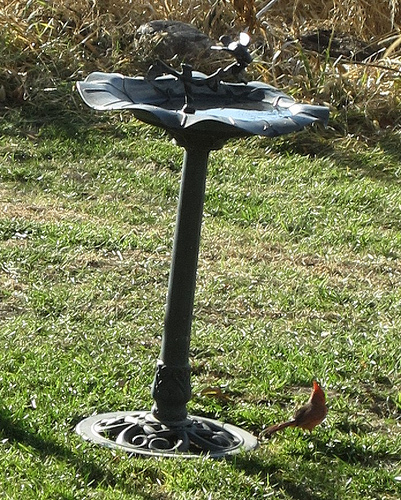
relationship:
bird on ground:
[267, 378, 339, 444] [238, 270, 356, 319]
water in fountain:
[188, 96, 237, 111] [97, 32, 274, 153]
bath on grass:
[76, 30, 329, 135] [42, 140, 116, 163]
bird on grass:
[267, 378, 339, 444] [42, 140, 116, 163]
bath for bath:
[76, 30, 329, 135] [76, 30, 329, 135]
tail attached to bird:
[255, 416, 297, 435] [267, 378, 339, 444]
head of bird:
[292, 378, 332, 403] [267, 378, 339, 444]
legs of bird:
[291, 423, 313, 440] [267, 378, 339, 444]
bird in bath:
[267, 378, 339, 444] [149, 99, 265, 145]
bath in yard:
[76, 30, 329, 135] [234, 150, 344, 218]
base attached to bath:
[140, 392, 188, 440] [76, 30, 329, 135]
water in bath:
[188, 96, 237, 111] [76, 30, 329, 135]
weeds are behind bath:
[277, 45, 312, 67] [76, 30, 329, 135]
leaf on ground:
[208, 386, 232, 401] [238, 270, 356, 319]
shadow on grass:
[277, 143, 319, 170] [42, 140, 116, 163]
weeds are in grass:
[277, 45, 312, 67] [42, 140, 116, 163]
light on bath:
[208, 97, 290, 130] [76, 30, 329, 135]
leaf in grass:
[208, 386, 232, 401] [42, 140, 116, 163]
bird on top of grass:
[267, 378, 339, 444] [42, 140, 116, 163]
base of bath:
[140, 392, 188, 440] [149, 99, 265, 145]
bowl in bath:
[36, 72, 227, 127] [76, 30, 329, 135]